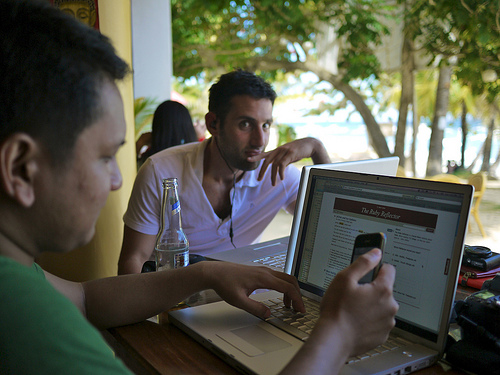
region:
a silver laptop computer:
[162, 168, 469, 373]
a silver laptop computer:
[197, 155, 402, 279]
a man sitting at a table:
[118, 72, 327, 284]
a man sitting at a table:
[0, 2, 397, 374]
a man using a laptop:
[0, 0, 477, 374]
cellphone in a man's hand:
[319, 232, 399, 350]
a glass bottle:
[153, 179, 188, 327]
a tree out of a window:
[171, 1, 498, 195]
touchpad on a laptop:
[220, 323, 292, 358]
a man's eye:
[237, 118, 249, 128]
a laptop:
[198, 304, 295, 348]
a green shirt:
[7, 273, 79, 363]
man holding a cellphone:
[351, 235, 388, 314]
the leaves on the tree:
[194, 8, 297, 68]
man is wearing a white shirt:
[245, 182, 271, 227]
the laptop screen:
[311, 175, 410, 235]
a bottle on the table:
[154, 180, 197, 258]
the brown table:
[144, 340, 196, 374]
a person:
[154, 103, 190, 136]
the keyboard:
[292, 305, 314, 334]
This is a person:
[117, 64, 339, 304]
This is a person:
[5, 7, 310, 374]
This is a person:
[132, 76, 199, 184]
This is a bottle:
[149, 170, 196, 336]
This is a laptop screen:
[288, 159, 478, 351]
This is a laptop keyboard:
[246, 265, 412, 370]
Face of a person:
[229, 99, 273, 169]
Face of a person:
[78, 74, 129, 254]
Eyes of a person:
[233, 117, 274, 134]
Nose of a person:
[250, 128, 268, 151]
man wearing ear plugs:
[154, 55, 305, 247]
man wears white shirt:
[126, 68, 313, 265]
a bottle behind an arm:
[148, 169, 204, 316]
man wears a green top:
[7, 15, 404, 373]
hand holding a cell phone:
[321, 219, 406, 359]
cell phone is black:
[341, 228, 392, 283]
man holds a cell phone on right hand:
[3, 0, 399, 374]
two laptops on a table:
[160, 140, 493, 374]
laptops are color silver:
[167, 151, 487, 373]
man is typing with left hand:
[24, 8, 481, 373]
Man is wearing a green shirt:
[2, 247, 134, 373]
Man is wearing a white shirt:
[122, 135, 316, 257]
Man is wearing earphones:
[204, 111, 269, 249]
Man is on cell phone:
[338, 229, 388, 289]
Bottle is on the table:
[151, 174, 190, 304]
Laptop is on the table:
[163, 165, 473, 372]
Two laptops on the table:
[168, 152, 477, 373]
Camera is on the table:
[456, 242, 498, 269]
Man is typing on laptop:
[142, 162, 476, 373]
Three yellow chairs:
[390, 164, 493, 238]